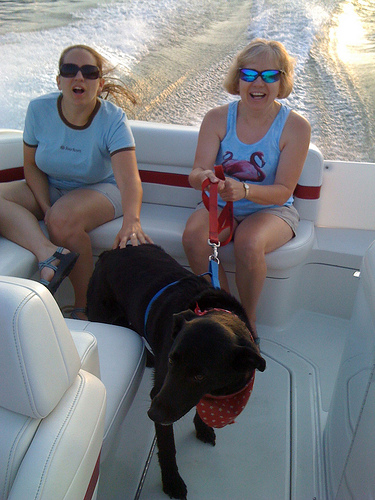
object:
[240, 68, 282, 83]
sunglasses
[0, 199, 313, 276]
boat seat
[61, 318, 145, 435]
seat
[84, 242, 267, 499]
dog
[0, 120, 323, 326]
chair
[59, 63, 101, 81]
sun shades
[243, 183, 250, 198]
watch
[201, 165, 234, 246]
leash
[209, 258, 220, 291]
blueleash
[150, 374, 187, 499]
leg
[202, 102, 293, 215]
shirt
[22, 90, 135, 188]
shirt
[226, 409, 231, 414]
part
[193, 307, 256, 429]
clothe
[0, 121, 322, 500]
cushions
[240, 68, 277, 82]
shades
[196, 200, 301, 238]
shorts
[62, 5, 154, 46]
bubbles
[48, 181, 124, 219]
shorts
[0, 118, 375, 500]
boat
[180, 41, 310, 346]
lady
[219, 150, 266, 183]
flamingos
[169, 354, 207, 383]
dog's eye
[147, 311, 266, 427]
head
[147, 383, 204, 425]
mouth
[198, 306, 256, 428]
bandana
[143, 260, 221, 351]
leash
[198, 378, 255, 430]
dots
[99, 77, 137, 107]
ponytail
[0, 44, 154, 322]
lady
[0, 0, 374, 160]
ocean